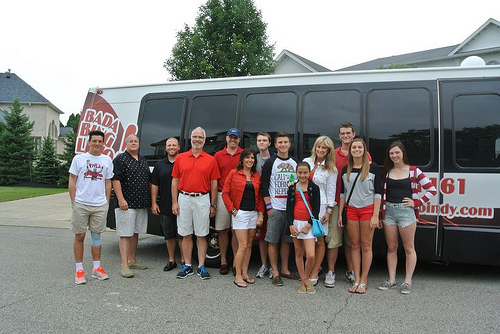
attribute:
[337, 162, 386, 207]
shirt — white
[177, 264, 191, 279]
sneaker — black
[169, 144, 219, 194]
shirt — red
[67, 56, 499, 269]
bus — white, long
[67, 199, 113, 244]
shorts — beige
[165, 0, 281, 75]
tall tree — green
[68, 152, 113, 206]
shirt — white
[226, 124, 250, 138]
hat — blue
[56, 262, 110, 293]
sneakers — bright orange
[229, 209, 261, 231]
skirt — short, white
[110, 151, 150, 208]
shirt — black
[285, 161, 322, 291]
girl — little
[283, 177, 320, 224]
sweater — black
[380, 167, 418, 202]
tank top — black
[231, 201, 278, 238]
shorts — white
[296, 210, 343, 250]
handbag — blue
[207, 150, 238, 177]
shirt — red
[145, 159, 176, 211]
shirt — black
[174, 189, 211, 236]
shorts — beige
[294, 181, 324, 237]
purse — blue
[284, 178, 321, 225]
jacket — black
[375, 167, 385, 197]
sleeve — black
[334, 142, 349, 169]
shirt — red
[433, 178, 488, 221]
writing — red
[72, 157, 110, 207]
t-shirt — white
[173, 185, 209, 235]
shorts — tan